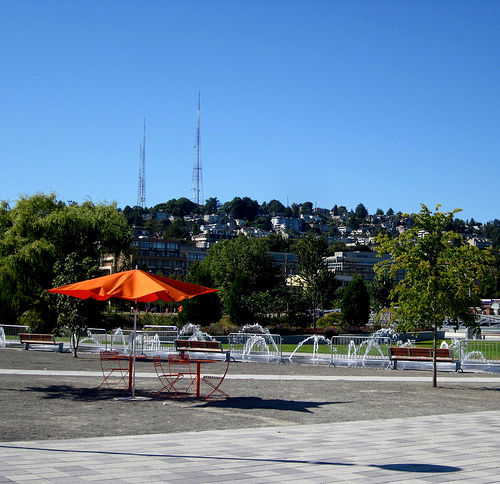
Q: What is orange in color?
A: An umbrella.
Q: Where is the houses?
A: In the hilltop.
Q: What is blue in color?
A: The sky.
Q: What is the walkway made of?
A: Pavers.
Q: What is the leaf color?
A: Green.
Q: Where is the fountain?
A: Park.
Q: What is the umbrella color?
A: Orange.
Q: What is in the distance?
A: Water.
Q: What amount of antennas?
A: Two.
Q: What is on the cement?
A: Shadow.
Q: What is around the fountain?
A: Trees.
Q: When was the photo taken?
A: In daytime.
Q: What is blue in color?
A: The sky.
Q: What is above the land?
A: The sky.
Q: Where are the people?
A: None in photo.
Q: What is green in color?
A: Trees.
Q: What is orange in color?
A: The umbrella.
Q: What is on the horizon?
A: Two towers.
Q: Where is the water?
A: Near the benches.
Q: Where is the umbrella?
A: Over the table.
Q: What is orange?
A: Umbrella.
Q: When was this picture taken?
A: During the day.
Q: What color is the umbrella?
A: Orange.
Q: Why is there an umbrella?
A: To make shade.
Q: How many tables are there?
A: Two.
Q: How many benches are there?
A: Three.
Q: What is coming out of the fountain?
A: Water.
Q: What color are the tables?
A: Orange.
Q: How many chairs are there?
A: 4.